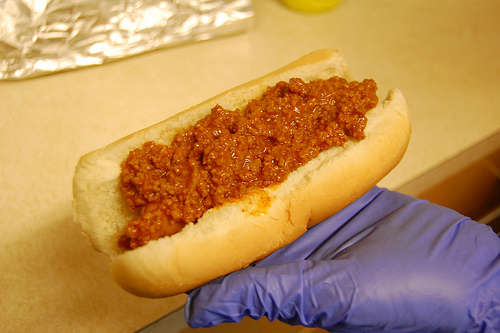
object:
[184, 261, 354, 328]
thumb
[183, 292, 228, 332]
tip finger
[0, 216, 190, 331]
shadow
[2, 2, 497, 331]
table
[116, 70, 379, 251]
chili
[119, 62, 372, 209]
chili dog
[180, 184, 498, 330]
hand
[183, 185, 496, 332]
wrinkles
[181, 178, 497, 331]
gloves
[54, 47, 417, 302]
hotdog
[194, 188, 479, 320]
person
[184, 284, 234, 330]
tip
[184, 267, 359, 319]
finger